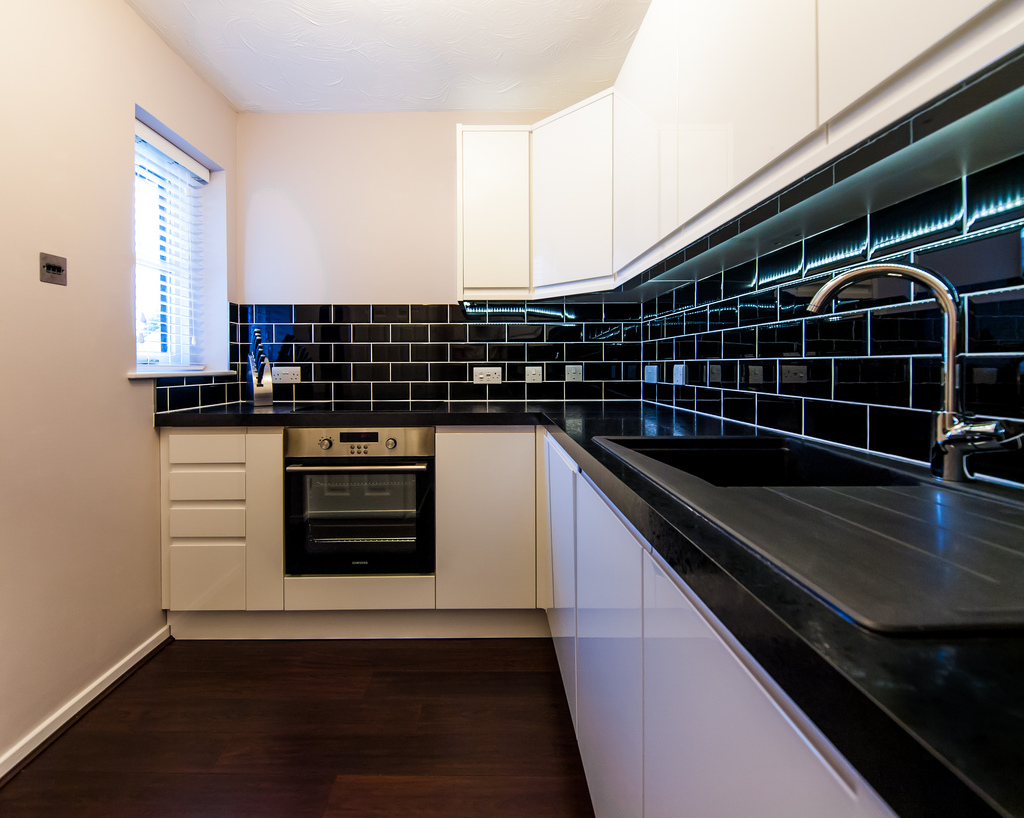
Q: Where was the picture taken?
A: Kitchen.